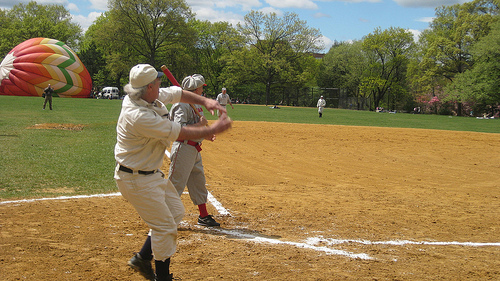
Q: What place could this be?
A: It is a park.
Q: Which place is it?
A: It is a park.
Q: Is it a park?
A: Yes, it is a park.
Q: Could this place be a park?
A: Yes, it is a park.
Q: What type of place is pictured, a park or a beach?
A: It is a park.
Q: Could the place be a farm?
A: No, it is a park.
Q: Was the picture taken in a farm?
A: No, the picture was taken in a park.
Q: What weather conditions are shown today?
A: It is cloudy.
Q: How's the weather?
A: It is cloudy.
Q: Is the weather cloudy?
A: Yes, it is cloudy.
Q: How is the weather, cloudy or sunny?
A: It is cloudy.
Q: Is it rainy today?
A: No, it is cloudy.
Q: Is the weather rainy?
A: No, it is cloudy.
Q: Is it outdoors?
A: Yes, it is outdoors.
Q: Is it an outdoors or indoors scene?
A: It is outdoors.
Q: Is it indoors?
A: No, it is outdoors.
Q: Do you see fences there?
A: No, there are no fences.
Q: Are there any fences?
A: No, there are no fences.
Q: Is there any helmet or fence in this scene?
A: No, there are no fences or helmets.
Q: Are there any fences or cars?
A: No, there are no fences or cars.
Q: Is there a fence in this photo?
A: No, there are no fences.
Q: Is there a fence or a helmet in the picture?
A: No, there are no fences or helmets.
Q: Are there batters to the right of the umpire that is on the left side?
A: Yes, there is a batter to the right of the umpire.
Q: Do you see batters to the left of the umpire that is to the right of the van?
A: No, the batter is to the right of the umpire.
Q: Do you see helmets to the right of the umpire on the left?
A: No, there is a batter to the right of the umpire.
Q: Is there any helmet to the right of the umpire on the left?
A: No, there is a batter to the right of the umpire.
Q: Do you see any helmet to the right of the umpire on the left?
A: No, there is a batter to the right of the umpire.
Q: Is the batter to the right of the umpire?
A: Yes, the batter is to the right of the umpire.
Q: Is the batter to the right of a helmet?
A: No, the batter is to the right of the umpire.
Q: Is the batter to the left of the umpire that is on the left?
A: No, the batter is to the right of the umpire.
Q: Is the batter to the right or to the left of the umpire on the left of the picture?
A: The batter is to the right of the umpire.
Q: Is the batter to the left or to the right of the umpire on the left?
A: The batter is to the right of the umpire.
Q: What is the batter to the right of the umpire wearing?
A: The batter is wearing uniforms.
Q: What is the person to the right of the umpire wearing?
A: The batter is wearing uniforms.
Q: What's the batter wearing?
A: The batter is wearing uniforms.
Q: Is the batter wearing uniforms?
A: Yes, the batter is wearing uniforms.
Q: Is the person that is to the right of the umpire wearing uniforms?
A: Yes, the batter is wearing uniforms.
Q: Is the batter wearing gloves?
A: No, the batter is wearing uniforms.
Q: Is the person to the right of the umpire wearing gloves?
A: No, the batter is wearing uniforms.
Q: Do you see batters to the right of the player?
A: Yes, there is a batter to the right of the player.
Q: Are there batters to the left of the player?
A: No, the batter is to the right of the player.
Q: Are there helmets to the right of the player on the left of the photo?
A: No, there is a batter to the right of the player.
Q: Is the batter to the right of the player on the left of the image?
A: Yes, the batter is to the right of the player.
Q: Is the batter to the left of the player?
A: No, the batter is to the right of the player.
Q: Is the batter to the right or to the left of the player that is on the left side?
A: The batter is to the right of the player.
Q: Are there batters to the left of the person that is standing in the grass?
A: Yes, there is a batter to the left of the person.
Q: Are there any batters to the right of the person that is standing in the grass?
A: No, the batter is to the left of the person.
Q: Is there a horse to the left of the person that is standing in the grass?
A: No, there is a batter to the left of the person.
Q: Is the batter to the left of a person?
A: Yes, the batter is to the left of a person.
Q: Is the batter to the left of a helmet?
A: No, the batter is to the left of a person.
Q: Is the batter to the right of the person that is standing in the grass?
A: No, the batter is to the left of the person.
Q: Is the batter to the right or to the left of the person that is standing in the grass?
A: The batter is to the left of the person.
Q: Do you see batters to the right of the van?
A: Yes, there is a batter to the right of the van.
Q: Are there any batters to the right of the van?
A: Yes, there is a batter to the right of the van.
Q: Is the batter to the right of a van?
A: Yes, the batter is to the right of a van.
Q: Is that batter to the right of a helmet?
A: No, the batter is to the right of a van.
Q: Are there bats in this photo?
A: Yes, there is a bat.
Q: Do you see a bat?
A: Yes, there is a bat.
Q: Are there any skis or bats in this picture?
A: Yes, there is a bat.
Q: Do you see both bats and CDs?
A: No, there is a bat but no cds.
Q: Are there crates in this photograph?
A: No, there are no crates.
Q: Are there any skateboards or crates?
A: No, there are no crates or skateboards.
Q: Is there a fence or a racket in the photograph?
A: No, there are no fences or rackets.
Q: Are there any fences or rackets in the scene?
A: No, there are no fences or rackets.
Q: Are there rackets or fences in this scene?
A: No, there are no fences or rackets.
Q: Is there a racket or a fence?
A: No, there are no fences or rackets.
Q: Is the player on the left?
A: Yes, the player is on the left of the image.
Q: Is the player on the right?
A: No, the player is on the left of the image.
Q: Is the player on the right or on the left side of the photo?
A: The player is on the left of the image.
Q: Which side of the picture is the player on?
A: The player is on the left of the image.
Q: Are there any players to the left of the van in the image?
A: Yes, there is a player to the left of the van.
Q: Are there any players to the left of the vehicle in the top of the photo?
A: Yes, there is a player to the left of the van.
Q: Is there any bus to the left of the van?
A: No, there is a player to the left of the van.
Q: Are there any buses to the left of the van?
A: No, there is a player to the left of the van.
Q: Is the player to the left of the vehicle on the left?
A: Yes, the player is to the left of the van.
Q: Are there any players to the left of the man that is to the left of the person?
A: Yes, there is a player to the left of the man.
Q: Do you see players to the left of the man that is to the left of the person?
A: Yes, there is a player to the left of the man.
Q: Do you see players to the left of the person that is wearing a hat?
A: Yes, there is a player to the left of the man.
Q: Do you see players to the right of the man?
A: No, the player is to the left of the man.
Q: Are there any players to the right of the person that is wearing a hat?
A: No, the player is to the left of the man.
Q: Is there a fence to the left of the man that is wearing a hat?
A: No, there is a player to the left of the man.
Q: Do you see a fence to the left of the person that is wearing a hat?
A: No, there is a player to the left of the man.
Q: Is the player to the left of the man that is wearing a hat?
A: Yes, the player is to the left of the man.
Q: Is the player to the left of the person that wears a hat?
A: Yes, the player is to the left of the man.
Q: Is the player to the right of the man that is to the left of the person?
A: No, the player is to the left of the man.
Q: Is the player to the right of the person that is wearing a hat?
A: No, the player is to the left of the man.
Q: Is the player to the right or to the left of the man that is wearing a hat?
A: The player is to the left of the man.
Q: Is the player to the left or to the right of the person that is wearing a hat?
A: The player is to the left of the man.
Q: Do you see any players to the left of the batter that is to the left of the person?
A: Yes, there is a player to the left of the batter.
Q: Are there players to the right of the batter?
A: No, the player is to the left of the batter.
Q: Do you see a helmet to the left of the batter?
A: No, there is a player to the left of the batter.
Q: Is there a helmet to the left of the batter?
A: No, there is a player to the left of the batter.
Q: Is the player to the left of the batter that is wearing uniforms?
A: Yes, the player is to the left of the batter.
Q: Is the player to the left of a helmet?
A: No, the player is to the left of the batter.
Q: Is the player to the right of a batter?
A: No, the player is to the left of a batter.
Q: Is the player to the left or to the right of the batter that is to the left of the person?
A: The player is to the left of the batter.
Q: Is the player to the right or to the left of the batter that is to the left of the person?
A: The player is to the left of the batter.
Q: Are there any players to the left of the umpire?
A: Yes, there is a player to the left of the umpire.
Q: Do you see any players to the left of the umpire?
A: Yes, there is a player to the left of the umpire.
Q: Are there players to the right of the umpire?
A: No, the player is to the left of the umpire.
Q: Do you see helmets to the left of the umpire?
A: No, there is a player to the left of the umpire.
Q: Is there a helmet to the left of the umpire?
A: No, there is a player to the left of the umpire.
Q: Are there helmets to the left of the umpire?
A: No, there is a player to the left of the umpire.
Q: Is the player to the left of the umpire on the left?
A: Yes, the player is to the left of the umpire.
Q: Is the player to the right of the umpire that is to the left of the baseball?
A: No, the player is to the left of the umpire.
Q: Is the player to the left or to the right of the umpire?
A: The player is to the left of the umpire.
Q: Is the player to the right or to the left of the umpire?
A: The player is to the left of the umpire.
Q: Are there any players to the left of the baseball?
A: Yes, there is a player to the left of the baseball.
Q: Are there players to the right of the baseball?
A: No, the player is to the left of the baseball.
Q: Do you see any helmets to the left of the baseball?
A: No, there is a player to the left of the baseball.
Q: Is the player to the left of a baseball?
A: Yes, the player is to the left of a baseball.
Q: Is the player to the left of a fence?
A: No, the player is to the left of a baseball.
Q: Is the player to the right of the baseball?
A: No, the player is to the left of the baseball.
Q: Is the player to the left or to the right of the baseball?
A: The player is to the left of the baseball.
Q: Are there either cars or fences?
A: No, there are no fences or cars.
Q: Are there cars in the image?
A: No, there are no cars.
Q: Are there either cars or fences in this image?
A: No, there are no cars or fences.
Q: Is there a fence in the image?
A: No, there are no fences.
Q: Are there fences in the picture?
A: No, there are no fences.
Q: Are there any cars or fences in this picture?
A: No, there are no fences or cars.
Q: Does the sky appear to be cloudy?
A: Yes, the sky is cloudy.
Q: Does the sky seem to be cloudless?
A: No, the sky is cloudy.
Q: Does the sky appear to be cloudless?
A: No, the sky is cloudy.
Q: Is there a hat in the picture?
A: Yes, there is a hat.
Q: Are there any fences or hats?
A: Yes, there is a hat.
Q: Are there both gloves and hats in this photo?
A: No, there is a hat but no gloves.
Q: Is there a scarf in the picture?
A: No, there are no scarves.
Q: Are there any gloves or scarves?
A: No, there are no scarves or gloves.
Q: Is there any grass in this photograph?
A: Yes, there is grass.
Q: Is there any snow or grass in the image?
A: Yes, there is grass.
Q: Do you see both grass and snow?
A: No, there is grass but no snow.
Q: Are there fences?
A: No, there are no fences.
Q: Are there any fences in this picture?
A: No, there are no fences.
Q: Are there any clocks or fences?
A: No, there are no fences or clocks.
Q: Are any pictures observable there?
A: No, there are no pictures.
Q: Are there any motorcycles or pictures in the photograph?
A: No, there are no pictures or motorcycles.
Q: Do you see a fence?
A: No, there are no fences.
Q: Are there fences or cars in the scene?
A: No, there are no fences or cars.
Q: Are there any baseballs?
A: Yes, there is a baseball.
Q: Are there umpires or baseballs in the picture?
A: Yes, there is a baseball.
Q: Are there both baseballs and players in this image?
A: Yes, there are both a baseball and a player.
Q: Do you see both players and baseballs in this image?
A: Yes, there are both a baseball and a player.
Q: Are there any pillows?
A: No, there are no pillows.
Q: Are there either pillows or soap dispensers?
A: No, there are no pillows or soap dispensers.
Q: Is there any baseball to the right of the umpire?
A: Yes, there is a baseball to the right of the umpire.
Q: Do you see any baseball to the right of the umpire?
A: Yes, there is a baseball to the right of the umpire.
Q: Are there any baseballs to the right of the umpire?
A: Yes, there is a baseball to the right of the umpire.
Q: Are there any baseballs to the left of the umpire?
A: No, the baseball is to the right of the umpire.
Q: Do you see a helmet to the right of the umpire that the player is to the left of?
A: No, there is a baseball to the right of the umpire.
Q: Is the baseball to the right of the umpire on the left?
A: Yes, the baseball is to the right of the umpire.